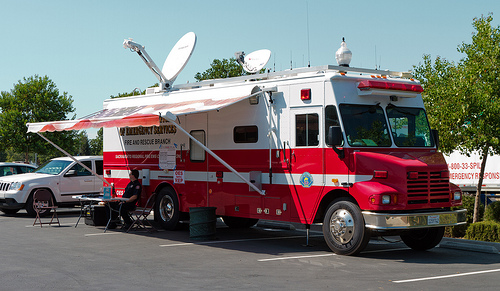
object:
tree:
[411, 12, 500, 228]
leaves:
[469, 78, 476, 83]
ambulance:
[87, 60, 470, 256]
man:
[105, 169, 142, 231]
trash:
[185, 205, 216, 240]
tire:
[320, 196, 373, 256]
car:
[0, 155, 102, 217]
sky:
[1, 2, 500, 131]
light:
[301, 88, 312, 101]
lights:
[369, 80, 387, 88]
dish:
[120, 30, 199, 89]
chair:
[31, 189, 61, 228]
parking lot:
[0, 208, 497, 291]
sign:
[173, 170, 185, 184]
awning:
[21, 86, 269, 194]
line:
[392, 268, 499, 285]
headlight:
[380, 193, 393, 206]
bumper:
[360, 208, 471, 231]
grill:
[403, 171, 453, 206]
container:
[82, 204, 118, 227]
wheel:
[397, 226, 444, 250]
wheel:
[151, 181, 180, 231]